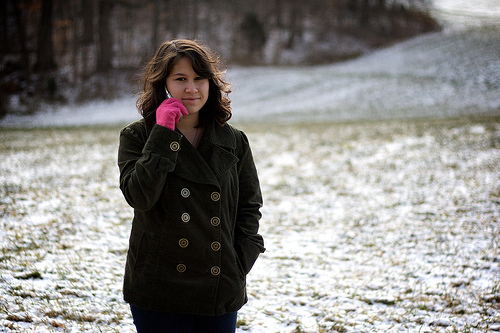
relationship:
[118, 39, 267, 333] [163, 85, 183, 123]
woman using a phone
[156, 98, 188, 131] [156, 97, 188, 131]
glove on a hand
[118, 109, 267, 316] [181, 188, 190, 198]
coat has a button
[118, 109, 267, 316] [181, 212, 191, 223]
coat has a button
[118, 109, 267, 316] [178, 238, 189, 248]
coat has a button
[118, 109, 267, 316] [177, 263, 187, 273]
coat has a button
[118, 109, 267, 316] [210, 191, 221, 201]
coat has a button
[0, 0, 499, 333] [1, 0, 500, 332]
grass covered with snow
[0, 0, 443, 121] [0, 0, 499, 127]
wooded area on a hillside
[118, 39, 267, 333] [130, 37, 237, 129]
woman has hair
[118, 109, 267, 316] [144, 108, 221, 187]
coat has a right lapel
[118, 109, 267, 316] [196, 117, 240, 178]
coat has a left lapel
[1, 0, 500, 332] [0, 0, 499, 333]
snow on grass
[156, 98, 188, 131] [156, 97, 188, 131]
glove on hand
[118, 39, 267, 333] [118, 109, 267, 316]
woman wearing a coat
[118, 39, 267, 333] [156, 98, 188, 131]
woman wearing a glove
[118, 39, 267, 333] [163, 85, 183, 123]
woman talking on a phone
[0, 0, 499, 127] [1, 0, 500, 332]
hillside covered with snow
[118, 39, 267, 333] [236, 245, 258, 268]
woman has a left hand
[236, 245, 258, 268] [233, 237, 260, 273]
left hand in pocket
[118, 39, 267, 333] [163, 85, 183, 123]
woman talking on phone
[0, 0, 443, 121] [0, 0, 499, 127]
wooded area behind hillside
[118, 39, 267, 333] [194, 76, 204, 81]
woman has a left eye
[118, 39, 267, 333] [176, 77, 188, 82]
woman has a right eye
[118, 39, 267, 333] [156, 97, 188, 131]
woman has a hand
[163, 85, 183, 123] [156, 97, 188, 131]
phone in hand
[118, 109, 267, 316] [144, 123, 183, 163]
coat has a cuff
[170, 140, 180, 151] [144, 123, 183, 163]
button on cuff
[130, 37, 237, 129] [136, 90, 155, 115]
hair has a curl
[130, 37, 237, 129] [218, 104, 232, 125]
hair has a curl